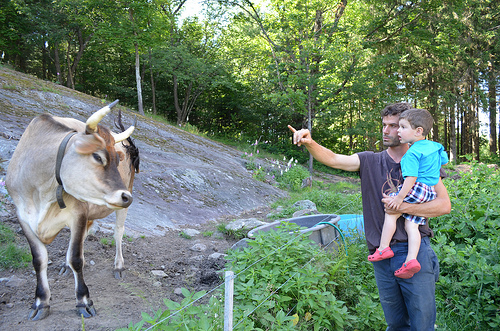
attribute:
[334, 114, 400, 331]
man — pointing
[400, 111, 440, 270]
kid — small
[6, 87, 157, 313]
cow — gray, black, brown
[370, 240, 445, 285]
shoes — red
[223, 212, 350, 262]
bucket — gray, plastic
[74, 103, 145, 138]
horns — gray tipped, sharp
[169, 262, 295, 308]
fence — wire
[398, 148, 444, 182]
shirt — blue, black, gray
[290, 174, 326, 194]
grass — green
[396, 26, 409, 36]
leaves — green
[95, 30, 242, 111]
trees — green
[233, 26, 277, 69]
sun — shining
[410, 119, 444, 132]
hair — brown, short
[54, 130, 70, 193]
collar — black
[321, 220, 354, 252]
hose — green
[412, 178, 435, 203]
shorts — plaid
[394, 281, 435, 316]
jeans — blue